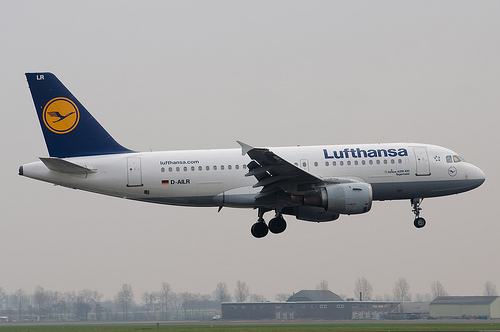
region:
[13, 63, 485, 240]
an airplane flying in the air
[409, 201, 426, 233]
the landing gear of a plane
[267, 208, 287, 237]
the landing gear of a plane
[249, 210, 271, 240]
the landing gear of a plane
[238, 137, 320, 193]
a wing of a plane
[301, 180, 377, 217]
an engine of a plane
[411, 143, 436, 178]
the door of a plane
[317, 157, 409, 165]
the windows on the side of a plane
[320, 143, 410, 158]
the blue letters on a plane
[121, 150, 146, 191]
a door of a plane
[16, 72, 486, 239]
white and blue plane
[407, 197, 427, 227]
front landing gear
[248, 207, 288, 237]
rear landing gear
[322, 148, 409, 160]
name of plane company painted in blue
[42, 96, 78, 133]
logo of plane on tail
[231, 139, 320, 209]
right wing on side of plane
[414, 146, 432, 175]
door on side of plane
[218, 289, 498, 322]
buildings located on side of runway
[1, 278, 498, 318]
row of trees near airport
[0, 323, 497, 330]
grassy field at airport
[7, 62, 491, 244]
A passenger plane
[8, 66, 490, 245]
A plane about to land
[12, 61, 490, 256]
Lufthansa Airlines plane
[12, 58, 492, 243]
A passenger get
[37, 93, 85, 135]
Logo for Lufthansa Airlines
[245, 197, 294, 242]
Rear wheels of landing gear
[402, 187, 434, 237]
Front wheel of landing gear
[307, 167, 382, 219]
Jet engine on a passenger airplane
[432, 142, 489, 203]
Cockpit of airplane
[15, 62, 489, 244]
Profile of airplane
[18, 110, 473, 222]
this is the plane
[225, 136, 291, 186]
this is the wing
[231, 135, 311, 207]
the wing is sharp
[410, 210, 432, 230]
this is the wheel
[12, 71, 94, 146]
this is the tail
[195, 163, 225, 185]
the plane is white in color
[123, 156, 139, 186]
the door is clodsed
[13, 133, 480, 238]
the plane is on air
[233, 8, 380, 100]
this is the sky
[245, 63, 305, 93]
the sky is grey in color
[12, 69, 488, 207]
big white airplane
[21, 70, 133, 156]
blue and yellow tail of airplane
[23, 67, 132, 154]
blue and yellow empennage of airplane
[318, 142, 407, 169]
blue letters on white airplane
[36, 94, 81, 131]
yelow symbol on empennage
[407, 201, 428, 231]
little front black wheel of airplane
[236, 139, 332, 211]
big right wing of airplane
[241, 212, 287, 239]
two little black wheels on airplane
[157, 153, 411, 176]
a bunch of windows on the right side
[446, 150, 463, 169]
pilot house of airplane